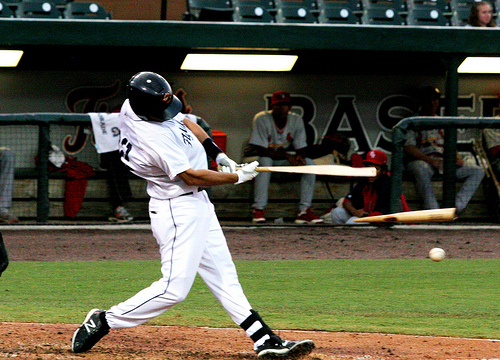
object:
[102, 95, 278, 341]
uniform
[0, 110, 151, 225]
fence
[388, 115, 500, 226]
fence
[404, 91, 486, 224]
man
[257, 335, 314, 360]
shoe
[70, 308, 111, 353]
shoe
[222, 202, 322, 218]
cleats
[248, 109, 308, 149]
white shirt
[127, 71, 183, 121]
baseball helmet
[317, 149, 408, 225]
man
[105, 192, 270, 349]
white pants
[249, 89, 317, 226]
man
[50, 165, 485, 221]
bench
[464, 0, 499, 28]
spectator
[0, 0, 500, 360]
gallery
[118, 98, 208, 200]
white jerssey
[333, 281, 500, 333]
lawn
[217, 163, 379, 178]
bat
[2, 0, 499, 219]
dugout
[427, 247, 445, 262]
wine bottle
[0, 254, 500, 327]
field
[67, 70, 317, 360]
man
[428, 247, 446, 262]
ball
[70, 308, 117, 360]
box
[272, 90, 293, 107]
cap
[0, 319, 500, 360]
dirt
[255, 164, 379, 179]
batter